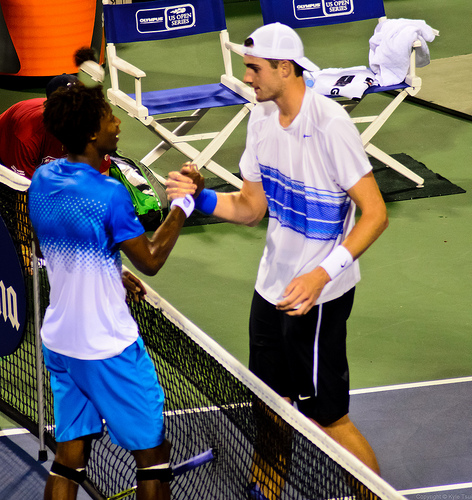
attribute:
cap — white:
[237, 16, 327, 77]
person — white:
[24, 80, 206, 498]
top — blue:
[28, 156, 150, 351]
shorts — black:
[238, 283, 359, 423]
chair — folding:
[85, 10, 309, 257]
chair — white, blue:
[94, 4, 288, 228]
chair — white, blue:
[207, 4, 436, 191]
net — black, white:
[96, 285, 314, 498]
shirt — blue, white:
[234, 85, 373, 309]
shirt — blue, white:
[27, 160, 143, 358]